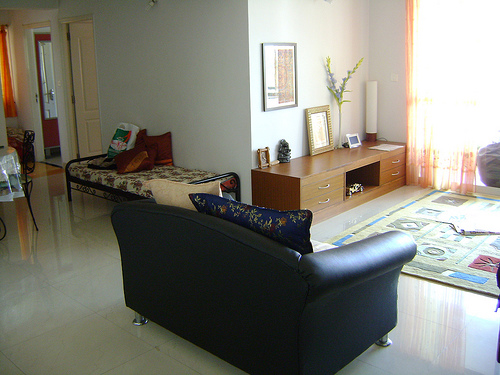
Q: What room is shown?
A: Living room.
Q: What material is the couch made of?
A: Leather.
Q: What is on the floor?
A: Rug.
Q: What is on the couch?
A: Pillows.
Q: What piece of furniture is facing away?
A: Couch.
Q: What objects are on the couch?
A: Pillows.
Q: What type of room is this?
A: Living room.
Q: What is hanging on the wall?
A: Artwork.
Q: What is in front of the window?
A: Curtains.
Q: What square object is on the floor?
A: Area rug.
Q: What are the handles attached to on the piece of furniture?
A: Drawers.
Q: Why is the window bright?
A: It is daytime.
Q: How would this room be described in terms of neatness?
A: Neat.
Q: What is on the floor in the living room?
A: A rug.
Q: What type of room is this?
A: Living room.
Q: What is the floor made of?
A: Tiles.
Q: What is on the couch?
A: Pillows.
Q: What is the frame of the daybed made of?
A: Metal.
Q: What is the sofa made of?
A: Leather.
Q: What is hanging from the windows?
A: Curtains.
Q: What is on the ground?
A: A rug.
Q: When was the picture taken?
A: Day time.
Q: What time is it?
A: Day time.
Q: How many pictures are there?
A: Four.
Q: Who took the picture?
A: Realtor.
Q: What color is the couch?
A: Brown.